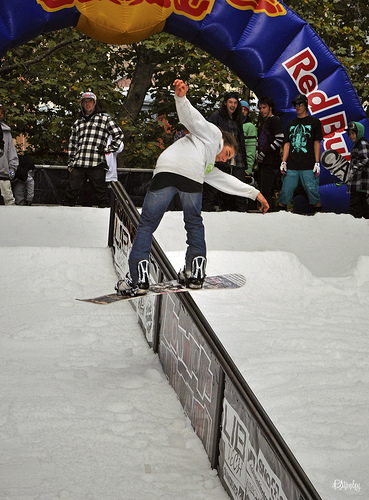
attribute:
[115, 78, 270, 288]
man — turned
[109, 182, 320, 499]
rail — black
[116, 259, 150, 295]
boot — black, white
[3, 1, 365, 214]
sign — here, advertisement, plastic, blue, yellow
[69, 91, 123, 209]
person — distant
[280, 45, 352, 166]
logo — red bull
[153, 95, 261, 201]
shirt — white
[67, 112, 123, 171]
jacket — black, white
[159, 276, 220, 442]
sign — hanging, advertisement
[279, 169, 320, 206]
shorts — green/blue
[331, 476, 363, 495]
name — here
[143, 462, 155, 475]
spot — tiny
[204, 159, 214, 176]
logo — green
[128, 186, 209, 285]
jeans — blue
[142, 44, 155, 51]
leaf — green